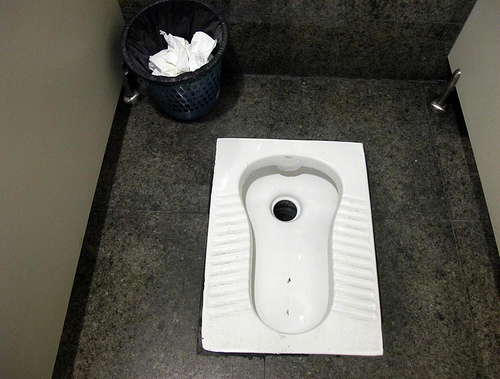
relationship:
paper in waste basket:
[146, 25, 218, 76] [120, 5, 227, 120]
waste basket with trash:
[117, 9, 232, 115] [140, 18, 216, 77]